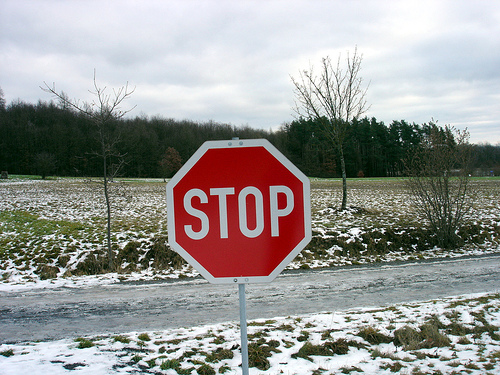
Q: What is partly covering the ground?
A: Snow.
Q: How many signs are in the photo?
A: One.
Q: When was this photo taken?
A: Daylight hours.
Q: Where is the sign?
A: Middle of photo.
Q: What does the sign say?
A: STOP.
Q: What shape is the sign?
A: Octagon.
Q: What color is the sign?
A: Red.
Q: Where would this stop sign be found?
A: At an intersection.